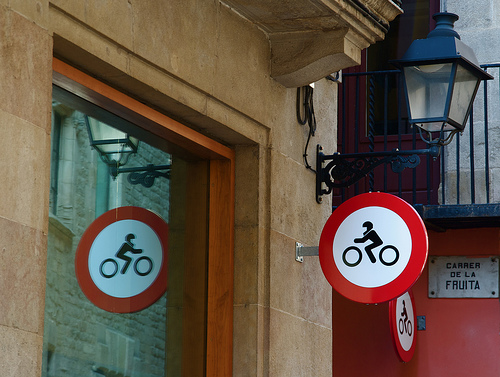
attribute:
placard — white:
[426, 254, 498, 299]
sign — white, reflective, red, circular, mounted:
[319, 190, 428, 306]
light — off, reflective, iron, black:
[389, 6, 492, 146]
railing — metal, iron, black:
[335, 62, 500, 209]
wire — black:
[295, 81, 319, 174]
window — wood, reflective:
[43, 53, 237, 376]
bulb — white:
[423, 116, 444, 146]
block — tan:
[266, 147, 333, 249]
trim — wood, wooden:
[53, 57, 242, 166]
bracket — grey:
[294, 241, 318, 263]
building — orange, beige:
[0, 1, 403, 377]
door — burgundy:
[333, 1, 440, 206]